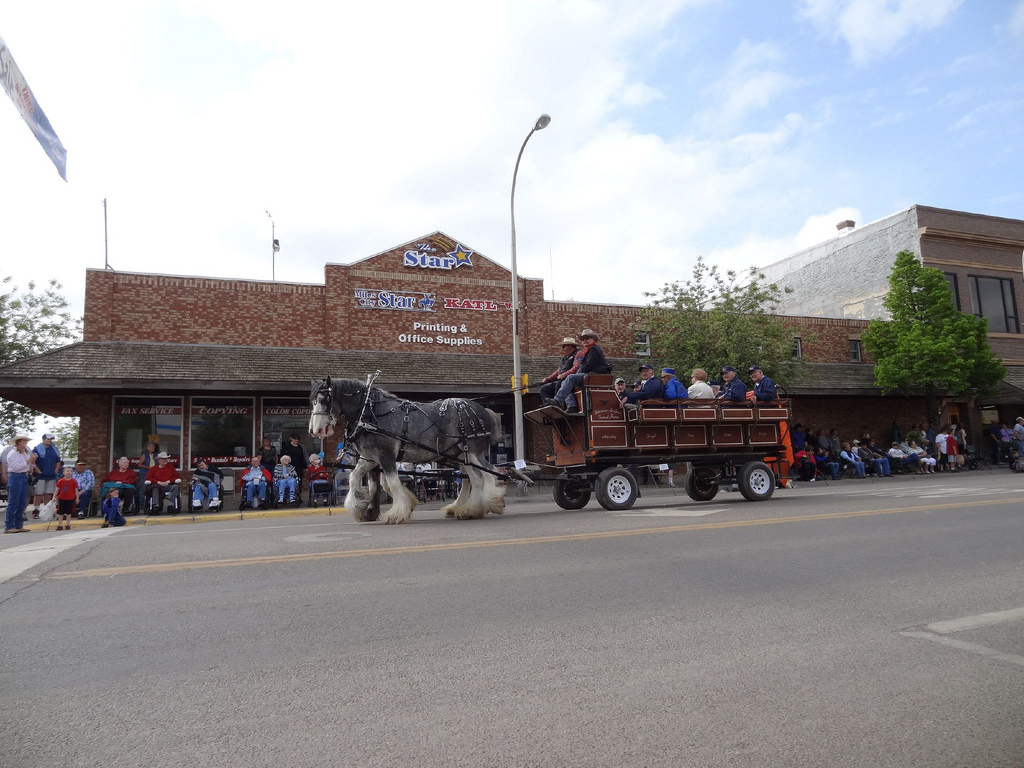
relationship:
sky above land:
[4, 4, 998, 229] [11, 495, 992, 725]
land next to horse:
[0, 577, 1019, 765] [305, 378, 517, 522]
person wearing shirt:
[1, 423, 33, 534] [6, 431, 41, 484]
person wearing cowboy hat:
[1, 423, 33, 534] [0, 407, 59, 462]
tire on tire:
[595, 469, 638, 510] [582, 467, 658, 519]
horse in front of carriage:
[306, 376, 504, 523] [533, 368, 797, 511]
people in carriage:
[555, 337, 781, 417] [551, 385, 804, 513]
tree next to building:
[860, 250, 1003, 466] [36, 232, 938, 483]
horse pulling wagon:
[313, 372, 503, 528] [527, 372, 789, 517]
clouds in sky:
[639, 213, 694, 252] [803, 36, 925, 188]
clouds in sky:
[728, 39, 827, 134] [792, 73, 978, 207]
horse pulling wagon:
[313, 372, 503, 528] [542, 383, 798, 520]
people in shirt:
[102, 456, 138, 513] [92, 464, 196, 501]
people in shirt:
[619, 365, 665, 409] [613, 349, 680, 419]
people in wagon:
[557, 329, 785, 406] [534, 371, 809, 499]